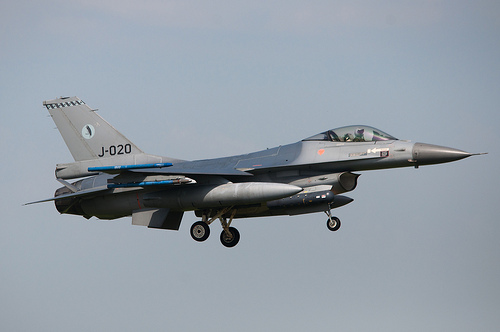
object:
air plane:
[21, 96, 488, 247]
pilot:
[353, 129, 366, 142]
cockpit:
[302, 125, 399, 142]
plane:
[0, 86, 480, 259]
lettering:
[98, 144, 132, 158]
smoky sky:
[0, 0, 499, 332]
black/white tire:
[327, 216, 341, 231]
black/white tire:
[190, 221, 211, 241]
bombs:
[107, 175, 197, 188]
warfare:
[145, 147, 393, 238]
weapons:
[142, 176, 303, 229]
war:
[210, 172, 308, 208]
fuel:
[143, 182, 353, 219]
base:
[0, 274, 500, 331]